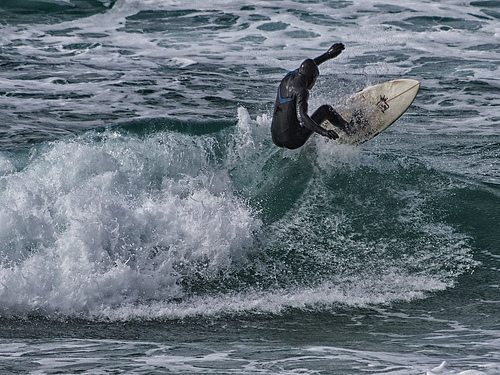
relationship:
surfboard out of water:
[315, 78, 421, 146] [0, 1, 499, 375]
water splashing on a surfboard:
[0, 1, 499, 375] [315, 78, 421, 146]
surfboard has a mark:
[315, 78, 421, 146] [375, 94, 389, 113]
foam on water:
[1, 1, 500, 375] [0, 1, 499, 375]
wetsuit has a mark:
[271, 43, 362, 149] [277, 69, 299, 104]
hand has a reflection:
[327, 43, 345, 59] [328, 47, 334, 54]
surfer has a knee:
[271, 43, 361, 150] [319, 104, 332, 110]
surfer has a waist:
[271, 43, 361, 150] [271, 121, 302, 133]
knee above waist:
[319, 104, 332, 110] [271, 121, 302, 133]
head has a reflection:
[298, 58, 319, 90] [300, 64, 304, 69]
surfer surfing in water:
[271, 43, 361, 150] [0, 1, 499, 375]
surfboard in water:
[315, 78, 421, 146] [0, 1, 499, 375]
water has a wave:
[0, 1, 499, 375] [0, 114, 499, 322]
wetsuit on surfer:
[271, 43, 362, 149] [271, 43, 361, 150]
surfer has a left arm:
[271, 43, 361, 150] [292, 43, 345, 74]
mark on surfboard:
[375, 94, 389, 113] [315, 78, 421, 146]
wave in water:
[0, 114, 499, 322] [0, 1, 499, 375]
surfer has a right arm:
[271, 43, 361, 150] [294, 86, 339, 140]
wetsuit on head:
[271, 43, 362, 149] [298, 58, 319, 90]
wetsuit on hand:
[271, 43, 362, 149] [327, 43, 345, 59]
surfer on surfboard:
[271, 43, 361, 150] [315, 78, 421, 146]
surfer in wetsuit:
[271, 43, 361, 150] [271, 43, 362, 149]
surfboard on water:
[315, 78, 421, 146] [0, 1, 499, 375]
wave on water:
[0, 114, 499, 322] [0, 1, 499, 375]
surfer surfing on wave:
[271, 43, 361, 150] [0, 114, 499, 322]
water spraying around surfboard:
[0, 1, 499, 375] [315, 78, 421, 146]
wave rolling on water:
[0, 114, 499, 322] [0, 1, 499, 375]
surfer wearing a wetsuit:
[271, 43, 361, 150] [271, 43, 362, 149]